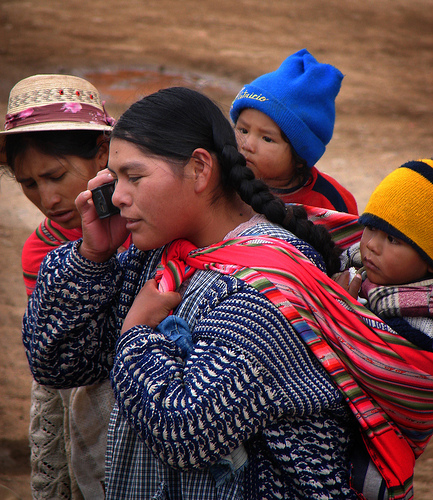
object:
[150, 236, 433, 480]
fabric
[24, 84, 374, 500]
woman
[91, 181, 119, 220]
phone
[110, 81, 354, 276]
hair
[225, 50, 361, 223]
child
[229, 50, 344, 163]
hat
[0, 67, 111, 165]
hat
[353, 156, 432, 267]
hat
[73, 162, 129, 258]
hand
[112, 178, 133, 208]
nose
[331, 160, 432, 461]
baby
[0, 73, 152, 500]
woman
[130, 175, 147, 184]
eye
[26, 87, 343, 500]
person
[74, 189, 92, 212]
finger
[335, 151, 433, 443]
toddler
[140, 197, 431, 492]
sling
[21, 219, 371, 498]
sweater